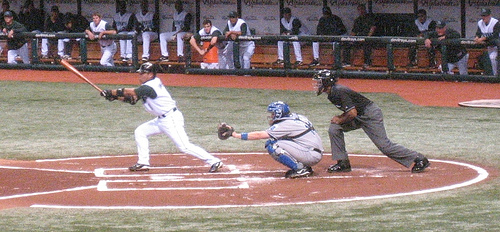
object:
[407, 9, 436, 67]
person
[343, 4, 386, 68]
person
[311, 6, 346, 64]
person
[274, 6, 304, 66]
person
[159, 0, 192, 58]
person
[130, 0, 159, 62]
person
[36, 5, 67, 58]
person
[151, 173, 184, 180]
plate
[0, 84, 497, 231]
field.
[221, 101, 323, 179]
catcher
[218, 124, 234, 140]
glove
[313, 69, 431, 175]
umpire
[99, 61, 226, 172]
player.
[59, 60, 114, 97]
bat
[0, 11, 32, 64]
players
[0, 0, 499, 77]
dugout.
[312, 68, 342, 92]
helmet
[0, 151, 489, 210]
lines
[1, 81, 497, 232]
grass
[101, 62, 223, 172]
batter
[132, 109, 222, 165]
pants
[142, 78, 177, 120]
jersey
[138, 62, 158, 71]
helmet.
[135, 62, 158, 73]
helmet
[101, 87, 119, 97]
hands.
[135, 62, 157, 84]
head.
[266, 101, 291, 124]
mask.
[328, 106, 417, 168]
pants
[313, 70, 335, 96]
mask.